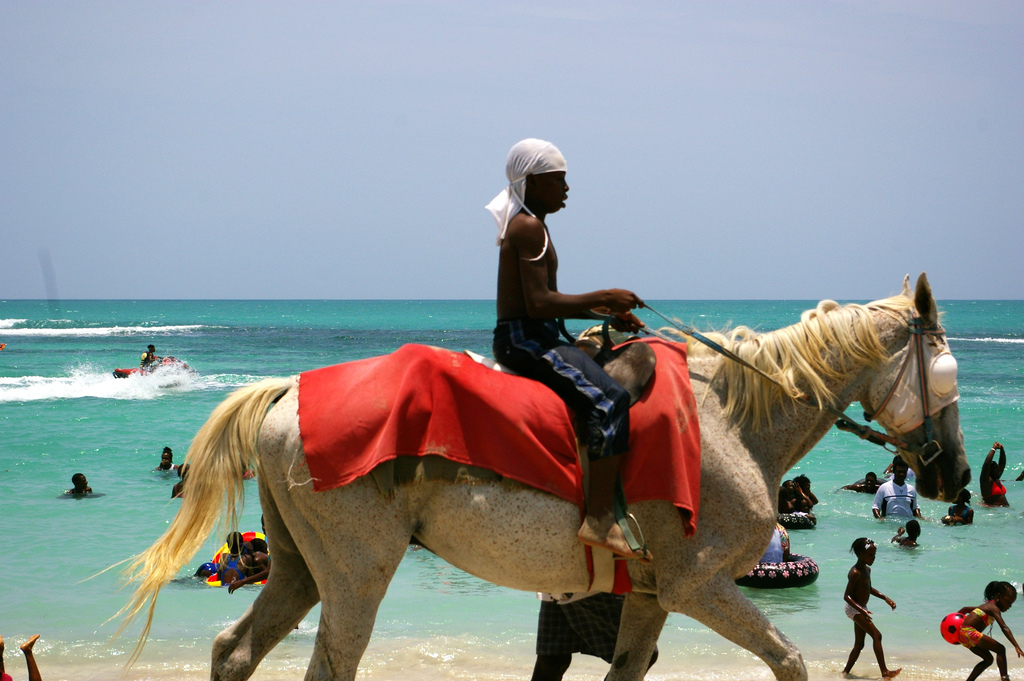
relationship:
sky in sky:
[0, 0, 1021, 302] [8, 4, 1021, 317]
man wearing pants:
[470, 130, 670, 555] [524, 324, 630, 502]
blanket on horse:
[277, 324, 726, 549] [134, 273, 966, 676]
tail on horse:
[101, 364, 299, 677] [134, 273, 966, 676]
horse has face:
[134, 273, 966, 676] [865, 284, 976, 503]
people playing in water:
[57, 443, 200, 508] [3, 296, 1021, 672]